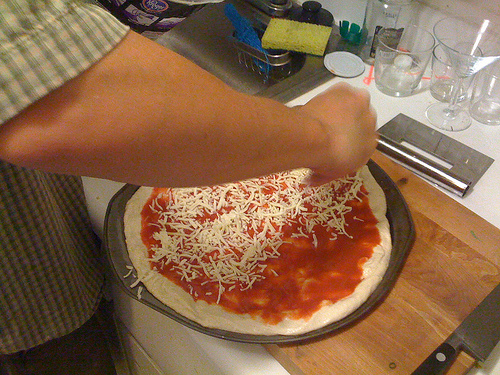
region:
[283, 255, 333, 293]
Sauce on the plate.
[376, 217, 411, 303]
A plate in the photo.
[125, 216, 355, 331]
An omellete in the picture.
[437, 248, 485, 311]
Wooden surface on the photo.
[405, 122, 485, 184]
Hinges in the photo.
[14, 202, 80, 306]
A plaid shirt in the photo.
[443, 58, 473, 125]
A glass in the photo.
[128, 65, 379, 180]
An arm in the photo.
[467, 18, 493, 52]
A spoon in the photo.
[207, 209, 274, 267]
Pasta on the plate.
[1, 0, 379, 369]
man making fresh pizza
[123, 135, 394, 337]
raw pizza with cheese and pizza sauce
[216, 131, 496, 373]
wooden board for chopping food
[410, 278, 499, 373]
sharp knife on the chopping block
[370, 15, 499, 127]
glasses on the kitchen counter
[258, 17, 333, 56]
dirty sponge on the kitchen sink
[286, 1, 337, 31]
black stopper for the kitchen sink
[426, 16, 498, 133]
empty martini glass on the counter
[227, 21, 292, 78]
silver sponge holder in the sink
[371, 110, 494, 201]
metal chopper for slicing food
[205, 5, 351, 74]
sponges near the edge of a metal sink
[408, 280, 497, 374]
a large knife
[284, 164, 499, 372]
a wood cutting board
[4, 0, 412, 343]
person sprinkling cheese on sauce-covered pizza dough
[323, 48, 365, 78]
lid cut from a can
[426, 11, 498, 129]
an empty martini glass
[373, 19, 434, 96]
a clear container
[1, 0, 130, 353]
person wearing a checked green shirt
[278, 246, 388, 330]
cheese-less section of dough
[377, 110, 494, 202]
a pizza dough cutter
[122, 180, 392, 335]
A pizza that is not cooked.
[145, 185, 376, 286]
Pieces of shredded mozzarella cheese.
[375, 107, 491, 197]
A stainless steel dough scraper.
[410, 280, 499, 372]
A chef's knife with a black handle.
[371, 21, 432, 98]
A small empty glass.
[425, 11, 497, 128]
An empty martini glass.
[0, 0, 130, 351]
The person is wearing a plaid shirt.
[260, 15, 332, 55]
A sponge for washing dishes.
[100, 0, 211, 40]
A bag of shredded mozzarella cheese.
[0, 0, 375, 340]
The person is making a pizza.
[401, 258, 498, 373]
Knife on cutting board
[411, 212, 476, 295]
Cutting board under pizza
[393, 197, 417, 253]
Pan that the pizza is on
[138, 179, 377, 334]
Pizza being made by man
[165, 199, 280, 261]
mozzarella cheese on pizza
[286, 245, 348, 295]
tomato sauce on pizza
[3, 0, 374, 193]
arm of man making pizza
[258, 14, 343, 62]
sponge on sink in background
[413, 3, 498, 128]
martini glass in background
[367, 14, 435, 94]
drink glass in background